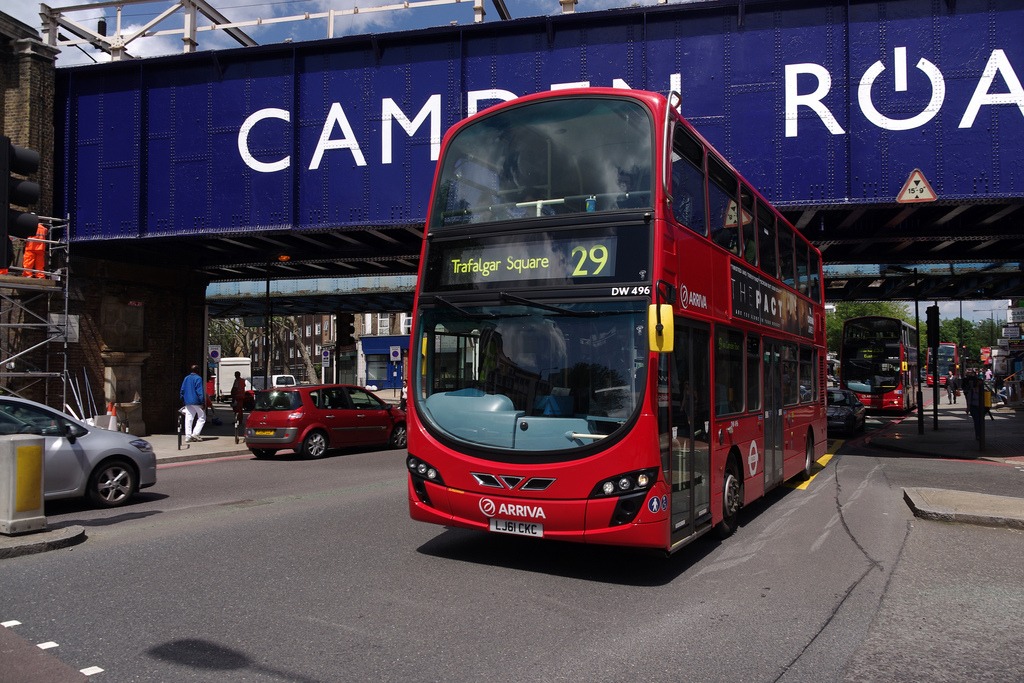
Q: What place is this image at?
A: It is at the road.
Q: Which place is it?
A: It is a road.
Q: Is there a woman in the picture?
A: No, there are no women.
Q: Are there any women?
A: No, there are no women.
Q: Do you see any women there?
A: No, there are no women.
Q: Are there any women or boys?
A: No, there are no women or boys.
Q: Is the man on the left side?
A: Yes, the man is on the left of the image.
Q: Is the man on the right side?
A: No, the man is on the left of the image.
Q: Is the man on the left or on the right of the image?
A: The man is on the left of the image.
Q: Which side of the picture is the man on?
A: The man is on the left of the image.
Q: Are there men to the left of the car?
A: Yes, there is a man to the left of the car.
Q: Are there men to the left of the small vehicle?
A: Yes, there is a man to the left of the car.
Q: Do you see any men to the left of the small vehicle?
A: Yes, there is a man to the left of the car.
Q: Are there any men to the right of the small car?
A: No, the man is to the left of the car.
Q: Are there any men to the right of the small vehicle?
A: No, the man is to the left of the car.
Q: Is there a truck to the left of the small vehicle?
A: No, there is a man to the left of the car.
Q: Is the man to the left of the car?
A: Yes, the man is to the left of the car.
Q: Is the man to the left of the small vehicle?
A: Yes, the man is to the left of the car.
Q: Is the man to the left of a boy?
A: No, the man is to the left of the car.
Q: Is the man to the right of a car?
A: No, the man is to the left of a car.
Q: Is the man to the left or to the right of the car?
A: The man is to the left of the car.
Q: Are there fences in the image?
A: No, there are no fences.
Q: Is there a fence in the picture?
A: No, there are no fences.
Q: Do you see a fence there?
A: No, there are no fences.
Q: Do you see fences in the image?
A: No, there are no fences.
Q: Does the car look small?
A: Yes, the car is small.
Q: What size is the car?
A: The car is small.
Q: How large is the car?
A: The car is small.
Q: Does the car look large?
A: No, the car is small.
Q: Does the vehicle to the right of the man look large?
A: No, the car is small.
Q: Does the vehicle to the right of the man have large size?
A: No, the car is small.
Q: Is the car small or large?
A: The car is small.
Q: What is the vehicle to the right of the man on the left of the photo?
A: The vehicle is a car.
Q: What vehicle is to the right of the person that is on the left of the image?
A: The vehicle is a car.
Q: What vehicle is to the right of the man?
A: The vehicle is a car.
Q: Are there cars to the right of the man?
A: Yes, there is a car to the right of the man.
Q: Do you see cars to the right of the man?
A: Yes, there is a car to the right of the man.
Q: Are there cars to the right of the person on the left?
A: Yes, there is a car to the right of the man.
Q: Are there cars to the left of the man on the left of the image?
A: No, the car is to the right of the man.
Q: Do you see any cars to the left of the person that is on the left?
A: No, the car is to the right of the man.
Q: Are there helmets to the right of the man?
A: No, there is a car to the right of the man.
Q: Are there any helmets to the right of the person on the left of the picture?
A: No, there is a car to the right of the man.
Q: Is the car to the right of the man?
A: Yes, the car is to the right of the man.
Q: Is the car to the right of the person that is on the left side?
A: Yes, the car is to the right of the man.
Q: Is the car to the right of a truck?
A: No, the car is to the right of the man.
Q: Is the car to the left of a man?
A: No, the car is to the right of a man.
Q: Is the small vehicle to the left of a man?
A: No, the car is to the right of a man.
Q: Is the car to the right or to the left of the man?
A: The car is to the right of the man.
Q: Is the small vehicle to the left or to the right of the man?
A: The car is to the right of the man.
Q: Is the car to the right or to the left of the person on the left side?
A: The car is to the right of the man.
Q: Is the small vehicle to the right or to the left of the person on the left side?
A: The car is to the right of the man.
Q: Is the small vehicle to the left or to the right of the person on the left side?
A: The car is to the right of the man.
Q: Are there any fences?
A: No, there are no fences.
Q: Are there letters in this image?
A: Yes, there are letters.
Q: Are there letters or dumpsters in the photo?
A: Yes, there are letters.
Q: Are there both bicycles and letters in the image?
A: No, there are letters but no bikes.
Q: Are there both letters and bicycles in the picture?
A: No, there are letters but no bikes.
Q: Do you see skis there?
A: No, there are no skis.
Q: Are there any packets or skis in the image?
A: No, there are no skis or packets.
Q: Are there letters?
A: Yes, there are letters.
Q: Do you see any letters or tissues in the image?
A: Yes, there are letters.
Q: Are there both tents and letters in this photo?
A: No, there are letters but no tents.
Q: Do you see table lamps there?
A: No, there are no table lamps.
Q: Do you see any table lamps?
A: No, there are no table lamps.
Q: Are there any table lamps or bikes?
A: No, there are no table lamps or bikes.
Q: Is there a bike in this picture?
A: No, there are no bikes.